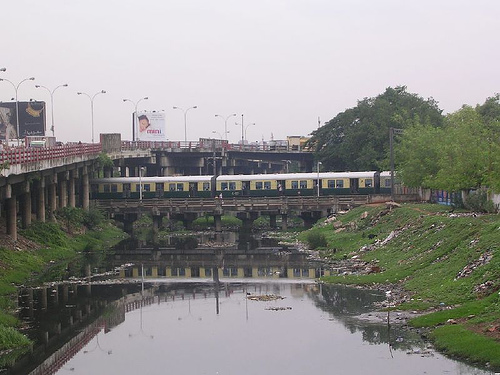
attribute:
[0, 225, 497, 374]
water — murky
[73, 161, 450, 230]
train — yellow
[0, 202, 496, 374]
water — calm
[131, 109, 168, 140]
billboard — advertise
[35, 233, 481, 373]
river — dirty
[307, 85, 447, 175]
trees — leafy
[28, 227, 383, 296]
water — dirty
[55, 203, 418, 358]
water — murky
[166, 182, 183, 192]
window — yellow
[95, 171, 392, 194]
train — green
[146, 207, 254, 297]
water — murky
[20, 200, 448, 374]
river — dirty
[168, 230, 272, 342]
river — dirty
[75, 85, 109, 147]
light pole — street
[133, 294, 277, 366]
water — murky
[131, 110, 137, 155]
pole — light, street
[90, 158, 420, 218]
train — green, yellow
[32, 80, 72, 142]
light pole — street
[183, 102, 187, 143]
pole — light, street